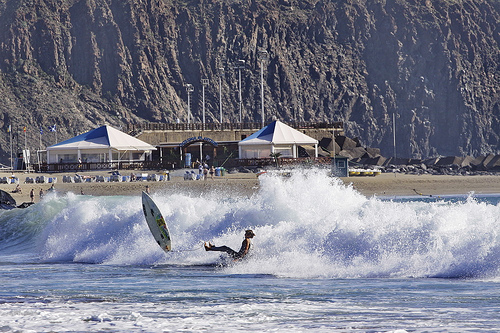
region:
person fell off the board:
[205, 228, 252, 257]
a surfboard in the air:
[139, 193, 171, 253]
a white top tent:
[46, 125, 154, 163]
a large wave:
[34, 175, 491, 279]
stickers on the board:
[155, 214, 164, 228]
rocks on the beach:
[378, 161, 487, 177]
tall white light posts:
[184, 47, 271, 122]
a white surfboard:
[139, 191, 176, 253]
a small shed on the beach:
[328, 154, 347, 176]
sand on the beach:
[337, 171, 494, 193]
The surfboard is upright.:
[86, 180, 280, 292]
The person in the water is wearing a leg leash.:
[119, 184, 272, 282]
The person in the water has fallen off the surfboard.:
[130, 185, 285, 277]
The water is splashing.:
[1, 163, 498, 331]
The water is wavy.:
[1, 155, 497, 330]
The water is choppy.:
[1, 153, 497, 330]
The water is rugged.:
[1, 155, 499, 332]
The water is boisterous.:
[1, 160, 496, 329]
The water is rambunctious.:
[3, 156, 498, 329]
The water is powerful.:
[1, 158, 498, 330]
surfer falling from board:
[180, 212, 261, 263]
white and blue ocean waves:
[297, 250, 339, 287]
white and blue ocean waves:
[373, 243, 393, 264]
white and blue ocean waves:
[437, 232, 472, 277]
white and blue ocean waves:
[290, 301, 316, 321]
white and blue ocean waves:
[187, 310, 227, 330]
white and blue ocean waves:
[39, 257, 87, 284]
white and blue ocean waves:
[339, 265, 379, 312]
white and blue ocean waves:
[184, 275, 216, 300]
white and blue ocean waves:
[368, 215, 424, 254]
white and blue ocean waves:
[328, 248, 395, 292]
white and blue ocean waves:
[372, 242, 432, 287]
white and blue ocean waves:
[275, 305, 306, 332]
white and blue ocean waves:
[362, 202, 397, 240]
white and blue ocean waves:
[202, 293, 246, 320]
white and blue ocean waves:
[62, 228, 102, 259]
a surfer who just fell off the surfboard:
[127, 171, 295, 298]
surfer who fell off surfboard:
[109, 180, 347, 305]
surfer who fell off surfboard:
[87, 164, 322, 296]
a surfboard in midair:
[122, 175, 183, 284]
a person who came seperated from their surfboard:
[30, 68, 440, 310]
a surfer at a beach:
[28, 26, 415, 300]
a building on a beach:
[23, 9, 390, 188]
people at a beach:
[7, 167, 74, 225]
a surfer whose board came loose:
[90, 175, 360, 330]